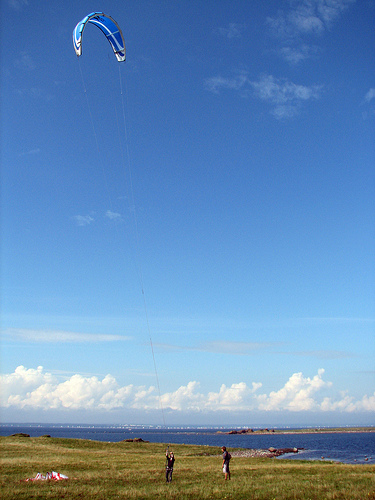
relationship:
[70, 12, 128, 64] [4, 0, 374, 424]
kite flying in sky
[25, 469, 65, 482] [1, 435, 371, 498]
kite laying in grass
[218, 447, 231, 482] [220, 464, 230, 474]
man wearing shorts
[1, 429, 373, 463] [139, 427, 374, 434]
water near field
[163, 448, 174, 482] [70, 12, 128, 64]
man managing kite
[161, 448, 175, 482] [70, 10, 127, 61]
man flying kite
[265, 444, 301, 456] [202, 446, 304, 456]
rocks on shore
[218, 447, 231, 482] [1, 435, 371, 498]
man standing on grass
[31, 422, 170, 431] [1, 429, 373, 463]
bridge crossing water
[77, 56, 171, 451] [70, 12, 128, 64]
string of a kite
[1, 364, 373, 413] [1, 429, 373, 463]
clouds over water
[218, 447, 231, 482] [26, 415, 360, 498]
man standing in field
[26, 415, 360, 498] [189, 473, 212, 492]
field of grass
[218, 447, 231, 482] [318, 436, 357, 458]
man standing by water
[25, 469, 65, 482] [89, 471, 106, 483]
kite on the ground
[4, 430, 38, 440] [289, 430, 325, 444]
rocks by the water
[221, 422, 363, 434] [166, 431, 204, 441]
island in the water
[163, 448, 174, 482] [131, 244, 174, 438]
man holding line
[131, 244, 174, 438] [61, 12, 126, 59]
line for kite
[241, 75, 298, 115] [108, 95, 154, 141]
cloud in the sky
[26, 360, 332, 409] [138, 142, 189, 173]
clouds in the sky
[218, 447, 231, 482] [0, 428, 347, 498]
man in a field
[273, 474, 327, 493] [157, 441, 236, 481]
grass near people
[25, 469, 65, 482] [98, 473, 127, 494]
kite laying on ground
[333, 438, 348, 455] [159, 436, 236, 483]
water next to people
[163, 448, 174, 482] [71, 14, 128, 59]
man flying kite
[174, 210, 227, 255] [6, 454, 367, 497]
sky above field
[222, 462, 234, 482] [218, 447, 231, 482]
shorts on a man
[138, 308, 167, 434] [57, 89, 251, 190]
string in the air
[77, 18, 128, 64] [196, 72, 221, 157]
kite flying high sky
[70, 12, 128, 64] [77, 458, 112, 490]
kite lying on ground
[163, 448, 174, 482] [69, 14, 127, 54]
man flying a kite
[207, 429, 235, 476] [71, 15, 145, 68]
man watching kite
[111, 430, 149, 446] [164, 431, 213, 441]
rock near water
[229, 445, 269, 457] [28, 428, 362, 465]
gravel near water